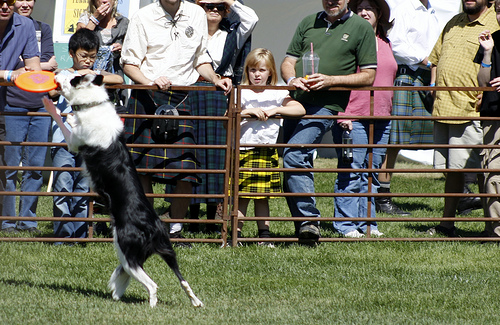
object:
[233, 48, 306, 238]
person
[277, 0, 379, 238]
person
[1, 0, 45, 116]
person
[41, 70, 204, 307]
dog